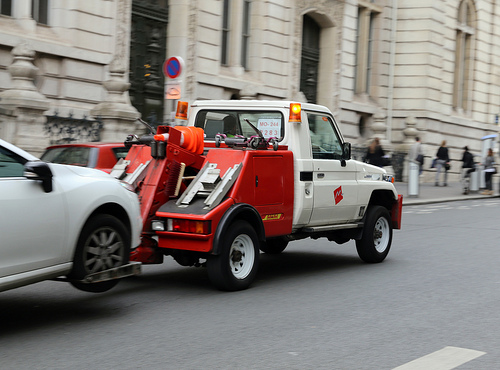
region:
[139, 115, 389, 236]
the tow truck is red and white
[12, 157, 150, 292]
towing a white car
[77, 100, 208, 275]
the truck is towing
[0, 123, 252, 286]
the white car is being towed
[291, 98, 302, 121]
A hazard light is on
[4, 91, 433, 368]
The truck is on the street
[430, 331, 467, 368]
the line is white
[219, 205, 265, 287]
the tire is black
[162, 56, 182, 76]
the sign is red and blue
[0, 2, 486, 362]
a crane towing a car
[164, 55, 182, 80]
a traffic sign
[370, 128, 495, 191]
some people walking on the street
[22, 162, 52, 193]
the rearview mirror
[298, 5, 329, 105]
the door of the building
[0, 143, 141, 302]
this damaged car is white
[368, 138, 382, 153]
this hair is blond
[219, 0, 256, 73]
two thin windows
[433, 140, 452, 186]
a sexy girl walking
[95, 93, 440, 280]
This is a tow truck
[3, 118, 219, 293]
The white car is being towed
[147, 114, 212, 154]
Several orange cones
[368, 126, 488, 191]
People walking on the sidewalk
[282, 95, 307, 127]
Light on the side of the car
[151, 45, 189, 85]
Blue and red stop sign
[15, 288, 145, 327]
Shadow underneath the white car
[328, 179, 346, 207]
Red logo on the side of the door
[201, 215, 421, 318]
Tow truck driving on the street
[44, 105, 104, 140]
A metal gate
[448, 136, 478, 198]
Person walking on the pavement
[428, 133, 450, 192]
Person walking on the pavement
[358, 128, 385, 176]
Person walking on the pavement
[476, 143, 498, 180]
Person walking on the pavement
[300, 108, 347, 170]
Small window of a truck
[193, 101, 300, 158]
Small window of a truck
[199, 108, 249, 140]
Small window of a truck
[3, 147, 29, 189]
Small window of a truck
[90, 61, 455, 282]
Red and whtie truck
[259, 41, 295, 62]
white stone on building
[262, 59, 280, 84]
white stone on building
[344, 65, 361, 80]
white stone on building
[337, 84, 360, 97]
white stone on building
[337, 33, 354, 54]
white stone on building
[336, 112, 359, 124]
white stone on building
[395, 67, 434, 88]
white stone on building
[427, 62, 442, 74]
white stone on building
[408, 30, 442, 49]
white stone on building